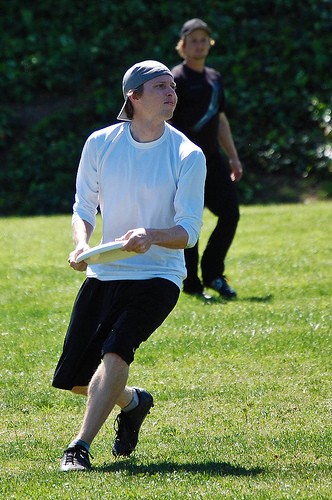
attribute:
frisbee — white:
[77, 236, 138, 268]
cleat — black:
[112, 389, 154, 456]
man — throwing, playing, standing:
[52, 59, 207, 476]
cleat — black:
[63, 446, 91, 475]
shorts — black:
[52, 275, 179, 389]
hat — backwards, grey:
[113, 55, 173, 122]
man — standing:
[179, 16, 244, 299]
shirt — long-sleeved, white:
[74, 122, 210, 288]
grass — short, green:
[2, 202, 331, 500]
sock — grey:
[122, 389, 139, 413]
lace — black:
[112, 413, 118, 435]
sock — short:
[70, 439, 89, 451]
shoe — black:
[207, 274, 236, 299]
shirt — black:
[172, 62, 226, 152]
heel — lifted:
[135, 389, 154, 408]